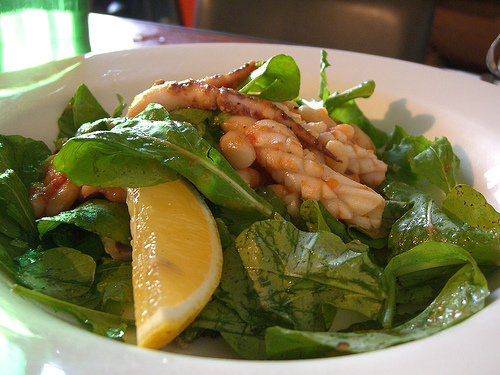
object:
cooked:
[212, 144, 385, 211]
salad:
[242, 212, 460, 362]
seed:
[155, 257, 190, 281]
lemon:
[104, 186, 226, 347]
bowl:
[0, 38, 499, 374]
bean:
[214, 127, 262, 172]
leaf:
[224, 206, 405, 336]